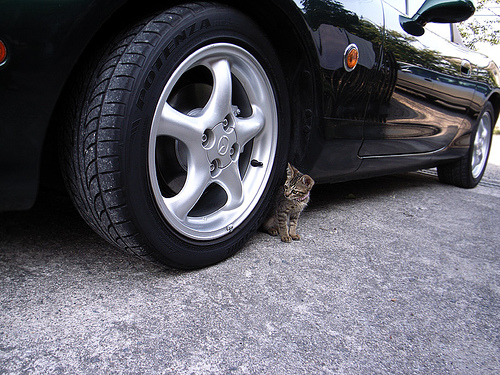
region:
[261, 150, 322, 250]
a kitten looking back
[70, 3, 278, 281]
a new, clean tire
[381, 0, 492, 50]
a car's side mirror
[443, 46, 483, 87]
a car's door handle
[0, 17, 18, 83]
a relfector on a car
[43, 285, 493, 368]
a smooth surface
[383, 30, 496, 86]
trees reflected in a car's body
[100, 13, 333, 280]
a kitten hiding behind a wheel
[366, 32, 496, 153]
a silver car reflected in a black car's body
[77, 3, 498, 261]
two tires and one cat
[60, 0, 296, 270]
Front driver side wheel of a black car.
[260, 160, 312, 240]
Kitten standing to the right of a wheel.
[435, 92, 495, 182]
Driver side back wheel on a black car.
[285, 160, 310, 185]
Ears on a cat's head.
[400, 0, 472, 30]
Driver side mirror on a black car.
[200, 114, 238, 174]
Four lug nuts on a front wheel.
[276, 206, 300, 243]
Two front legs of a cat.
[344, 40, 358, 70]
Orange round light on the driver side of the car.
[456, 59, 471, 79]
Door handle on the driver side of a black car.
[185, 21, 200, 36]
The letter Z on a tire.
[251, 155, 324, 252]
a kitten beside the tire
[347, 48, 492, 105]
reflection of a car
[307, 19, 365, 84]
orange light on the side of the car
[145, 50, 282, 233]
a clean chrome rim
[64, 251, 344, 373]
road made of gravel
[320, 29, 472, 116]
trees in the reflection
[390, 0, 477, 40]
the rear view mirror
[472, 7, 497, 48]
the sky is cloudy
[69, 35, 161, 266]
the tire is white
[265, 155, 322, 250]
the cat has stripes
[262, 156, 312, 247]
Cat sitting on ground.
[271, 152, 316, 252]
The cat is brown.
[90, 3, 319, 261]
The cat is next to the tire.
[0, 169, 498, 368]
The ground is grey.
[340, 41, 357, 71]
The light is orange.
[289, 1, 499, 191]
The car is black.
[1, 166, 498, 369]
The ground is gravel.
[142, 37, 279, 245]
The hubcap is silver.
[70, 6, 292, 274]
The wheel is round.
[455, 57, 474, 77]
Handle on the car.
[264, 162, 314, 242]
a kitten hiding behind the car tire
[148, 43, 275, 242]
an aluminum wheel cover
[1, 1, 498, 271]
a black 2 door coup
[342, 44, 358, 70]
a turning signal light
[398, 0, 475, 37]
the driver side rear view mirror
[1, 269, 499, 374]
the street is made of asphalt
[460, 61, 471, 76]
the door handle of the car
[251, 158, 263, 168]
the tire air valve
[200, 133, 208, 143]
the lug nuts of the car wheel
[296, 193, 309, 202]
the kitten has a red collar on